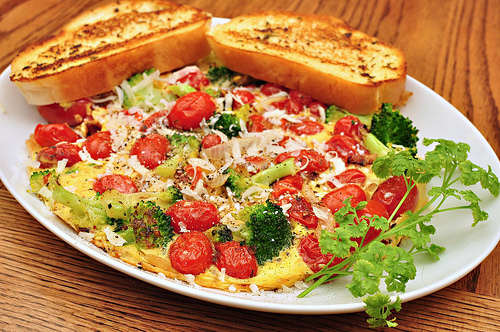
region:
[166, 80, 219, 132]
a red tomato slice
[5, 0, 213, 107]
a slice of bread on the plate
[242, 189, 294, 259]
a piece of broccoli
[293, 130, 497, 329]
a sprig of parsley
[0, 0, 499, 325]
a white porcelain plate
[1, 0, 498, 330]
a brown wooden table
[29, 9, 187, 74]
seasoning on the bread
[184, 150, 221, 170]
a shred of cheese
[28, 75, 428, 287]
yellow eggs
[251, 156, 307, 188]
a broccoli stem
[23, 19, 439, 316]
a plate containing food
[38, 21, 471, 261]
a delicious looking food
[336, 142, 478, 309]
a decorative item in plate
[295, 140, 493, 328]
a small leaf on plate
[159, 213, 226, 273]
a small piece of cherry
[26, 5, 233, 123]
a piece of bread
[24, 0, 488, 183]
two pieces of bread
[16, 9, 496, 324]
a plate containing food items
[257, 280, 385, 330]
a part of the plate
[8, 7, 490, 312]
a white plate on table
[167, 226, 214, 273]
the food is red in color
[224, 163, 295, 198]
the food is green in color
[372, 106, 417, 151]
the food is green in color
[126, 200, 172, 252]
the food is green in color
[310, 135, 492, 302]
the food is green in color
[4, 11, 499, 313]
the plate is white in color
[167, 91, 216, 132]
the food is red in color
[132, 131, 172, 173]
the food is red in color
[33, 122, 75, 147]
the food is red in color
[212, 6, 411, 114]
a slice of bread on the dish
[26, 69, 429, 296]
large vegetable frittata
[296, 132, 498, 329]
parsley on oval white plate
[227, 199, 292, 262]
broccoli on frittata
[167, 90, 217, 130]
red cherry tomato on frittata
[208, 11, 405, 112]
piece of toast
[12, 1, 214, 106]
piece of toast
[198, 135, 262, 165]
piece of onion on frittata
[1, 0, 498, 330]
oak table under plate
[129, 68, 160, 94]
shred of white cheese on frittata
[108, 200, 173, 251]
piece of browned broccoli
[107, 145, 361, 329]
the plate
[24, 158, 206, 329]
the plate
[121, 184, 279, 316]
the plate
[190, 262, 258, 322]
the plate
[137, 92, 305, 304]
the plate